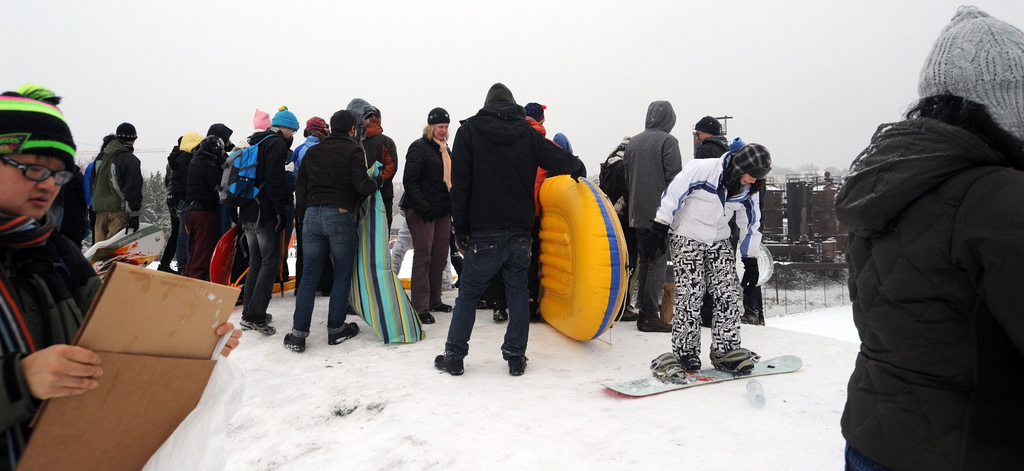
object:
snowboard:
[595, 341, 809, 406]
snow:
[143, 266, 868, 467]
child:
[230, 106, 298, 333]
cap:
[271, 107, 299, 128]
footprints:
[290, 373, 414, 465]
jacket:
[447, 129, 542, 242]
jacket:
[451, 135, 552, 225]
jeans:
[288, 209, 387, 342]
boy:
[647, 144, 775, 379]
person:
[832, 0, 1024, 471]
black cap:
[0, 86, 87, 166]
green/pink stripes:
[0, 98, 71, 155]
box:
[22, 259, 239, 467]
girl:
[832, 6, 1023, 468]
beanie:
[915, 4, 1021, 140]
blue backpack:
[217, 146, 258, 222]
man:
[621, 96, 682, 331]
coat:
[624, 99, 681, 228]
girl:
[291, 132, 360, 257]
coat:
[295, 136, 383, 212]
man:
[5, 87, 237, 462]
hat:
[692, 117, 724, 135]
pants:
[663, 231, 759, 369]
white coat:
[657, 137, 766, 260]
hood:
[643, 101, 675, 131]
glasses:
[0, 156, 79, 186]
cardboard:
[13, 259, 241, 468]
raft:
[539, 162, 629, 346]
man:
[430, 85, 554, 376]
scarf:
[443, 131, 457, 193]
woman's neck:
[421, 128, 451, 149]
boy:
[2, 83, 243, 466]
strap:
[255, 130, 279, 204]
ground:
[170, 262, 855, 471]